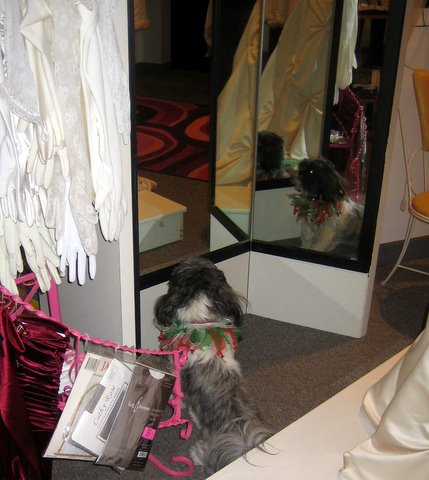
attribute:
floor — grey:
[214, 307, 348, 422]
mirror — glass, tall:
[244, 2, 380, 292]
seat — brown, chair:
[378, 62, 428, 268]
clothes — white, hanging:
[0, 5, 116, 285]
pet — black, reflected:
[112, 214, 277, 469]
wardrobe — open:
[13, 12, 125, 450]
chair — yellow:
[407, 69, 425, 337]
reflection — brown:
[327, 95, 377, 178]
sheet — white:
[298, 366, 428, 460]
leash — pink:
[43, 293, 193, 438]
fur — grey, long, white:
[207, 356, 225, 399]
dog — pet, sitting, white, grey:
[157, 258, 273, 464]